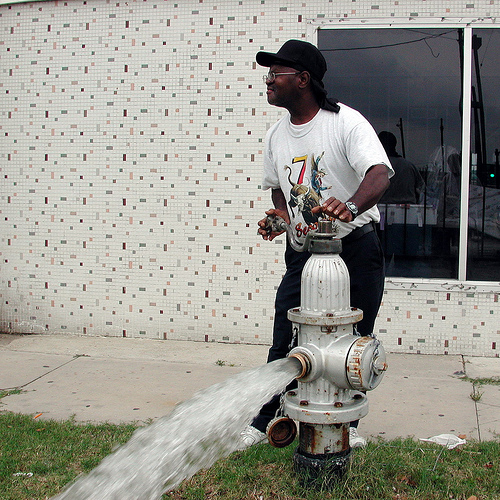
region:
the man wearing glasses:
[240, 25, 400, 426]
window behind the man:
[322, 31, 497, 288]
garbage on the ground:
[410, 421, 487, 452]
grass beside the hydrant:
[10, 421, 496, 496]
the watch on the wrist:
[337, 196, 362, 216]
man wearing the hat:
[242, 37, 337, 77]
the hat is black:
[240, 41, 333, 75]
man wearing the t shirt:
[267, 103, 395, 240]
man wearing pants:
[267, 225, 377, 430]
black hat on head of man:
[252, 36, 324, 68]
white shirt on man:
[252, 106, 393, 238]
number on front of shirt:
[288, 149, 309, 194]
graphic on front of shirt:
[271, 151, 346, 239]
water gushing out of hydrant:
[108, 359, 303, 499]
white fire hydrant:
[227, 209, 375, 487]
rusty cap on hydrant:
[262, 412, 296, 447]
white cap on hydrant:
[331, 336, 388, 400]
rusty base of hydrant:
[291, 418, 355, 480]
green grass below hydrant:
[240, 453, 465, 497]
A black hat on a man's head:
[255, 38, 327, 83]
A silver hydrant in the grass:
[261, 211, 386, 476]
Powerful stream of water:
[84, 353, 299, 498]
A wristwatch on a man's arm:
[343, 199, 359, 214]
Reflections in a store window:
[316, 25, 463, 285]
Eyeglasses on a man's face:
[258, 70, 300, 80]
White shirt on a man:
[259, 105, 394, 250]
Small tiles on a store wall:
[2, 22, 256, 334]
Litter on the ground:
[421, 430, 468, 452]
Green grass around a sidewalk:
[1, 425, 486, 499]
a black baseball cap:
[250, 38, 331, 79]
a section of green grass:
[360, 431, 497, 498]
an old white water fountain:
[263, 218, 388, 483]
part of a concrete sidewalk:
[0, 325, 266, 432]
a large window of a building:
[315, 28, 472, 278]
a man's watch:
[342, 195, 362, 214]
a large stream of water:
[57, 352, 294, 497]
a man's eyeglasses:
[261, 69, 298, 80]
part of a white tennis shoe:
[347, 420, 367, 446]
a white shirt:
[255, 103, 392, 247]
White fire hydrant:
[268, 221, 385, 473]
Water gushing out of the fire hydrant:
[37, 359, 304, 499]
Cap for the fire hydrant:
[262, 412, 297, 452]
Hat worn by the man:
[254, 39, 341, 116]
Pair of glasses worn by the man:
[260, 66, 300, 81]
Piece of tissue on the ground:
[414, 426, 469, 448]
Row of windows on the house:
[312, 16, 494, 283]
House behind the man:
[1, 1, 498, 356]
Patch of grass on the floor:
[1, 411, 498, 498]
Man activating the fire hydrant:
[241, 36, 393, 440]